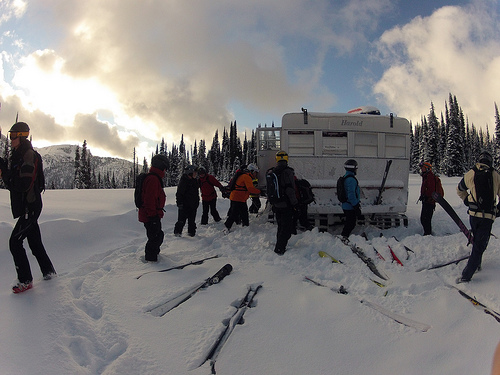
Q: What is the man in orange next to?
A: Snowcat.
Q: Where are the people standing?
A: In snow.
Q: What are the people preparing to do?
A: Ski.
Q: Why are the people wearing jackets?
A: Cold.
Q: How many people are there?
A: Ten.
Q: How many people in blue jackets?
A: One person.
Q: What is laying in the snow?
A: Skis and ski poles.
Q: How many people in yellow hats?
A: One.